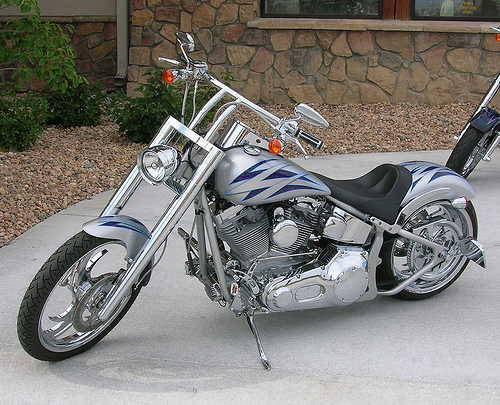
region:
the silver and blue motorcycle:
[15, 23, 485, 368]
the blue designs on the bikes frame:
[231, 164, 302, 196]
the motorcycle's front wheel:
[17, 232, 144, 358]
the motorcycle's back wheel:
[372, 192, 482, 302]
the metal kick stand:
[243, 311, 270, 369]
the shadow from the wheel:
[45, 353, 265, 400]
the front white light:
[135, 143, 175, 184]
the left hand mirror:
[287, 99, 334, 129]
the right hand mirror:
[171, 30, 201, 50]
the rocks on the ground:
[6, 147, 96, 195]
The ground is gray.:
[331, 337, 471, 390]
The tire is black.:
[26, 232, 112, 335]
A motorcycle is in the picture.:
[35, 54, 482, 329]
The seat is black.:
[308, 155, 423, 230]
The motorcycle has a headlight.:
[127, 135, 207, 209]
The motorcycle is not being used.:
[101, 27, 476, 317]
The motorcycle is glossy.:
[114, 32, 478, 318]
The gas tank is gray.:
[208, 132, 338, 217]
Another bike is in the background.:
[434, 20, 499, 185]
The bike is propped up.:
[171, 166, 309, 384]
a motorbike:
[105, 104, 337, 378]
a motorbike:
[120, 188, 241, 349]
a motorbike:
[176, 201, 306, 401]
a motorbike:
[147, 71, 327, 269]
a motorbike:
[297, 200, 328, 301]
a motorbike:
[192, 144, 243, 241]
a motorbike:
[190, 137, 420, 367]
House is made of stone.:
[187, 17, 487, 114]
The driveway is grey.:
[327, 322, 428, 394]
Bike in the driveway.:
[21, 64, 462, 329]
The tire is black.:
[48, 228, 152, 369]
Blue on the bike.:
[233, 158, 319, 217]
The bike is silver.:
[78, 126, 471, 334]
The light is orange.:
[258, 132, 297, 167]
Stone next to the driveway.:
[8, 155, 87, 195]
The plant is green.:
[118, 68, 223, 145]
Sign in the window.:
[423, 1, 497, 19]